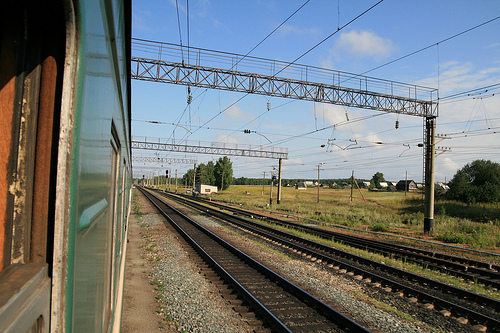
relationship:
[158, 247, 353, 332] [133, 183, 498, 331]
gray ballast between tracks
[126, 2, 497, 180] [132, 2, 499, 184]
cloud in sky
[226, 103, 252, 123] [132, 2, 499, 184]
clouds in sky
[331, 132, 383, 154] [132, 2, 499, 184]
clouds in sky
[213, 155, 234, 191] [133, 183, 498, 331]
green tree next to tracks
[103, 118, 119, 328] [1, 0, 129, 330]
window on green train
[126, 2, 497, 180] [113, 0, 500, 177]
cloud in blue sky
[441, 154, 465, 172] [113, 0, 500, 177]
cloud in blue sky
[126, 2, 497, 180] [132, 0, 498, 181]
cloud in blue sky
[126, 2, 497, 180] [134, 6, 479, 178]
cloud in sky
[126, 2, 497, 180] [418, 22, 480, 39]
cloud in sky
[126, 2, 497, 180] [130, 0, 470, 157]
cloud in sky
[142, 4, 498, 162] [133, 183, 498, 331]
power lines over tracks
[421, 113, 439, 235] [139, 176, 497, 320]
pole near tracks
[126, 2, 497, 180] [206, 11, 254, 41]
cloud in sky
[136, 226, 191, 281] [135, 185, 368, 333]
gravel lining track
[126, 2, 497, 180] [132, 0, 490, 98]
cloud in blue sky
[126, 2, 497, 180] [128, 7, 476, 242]
cloud in sky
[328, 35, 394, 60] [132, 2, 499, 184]
cloud in sky